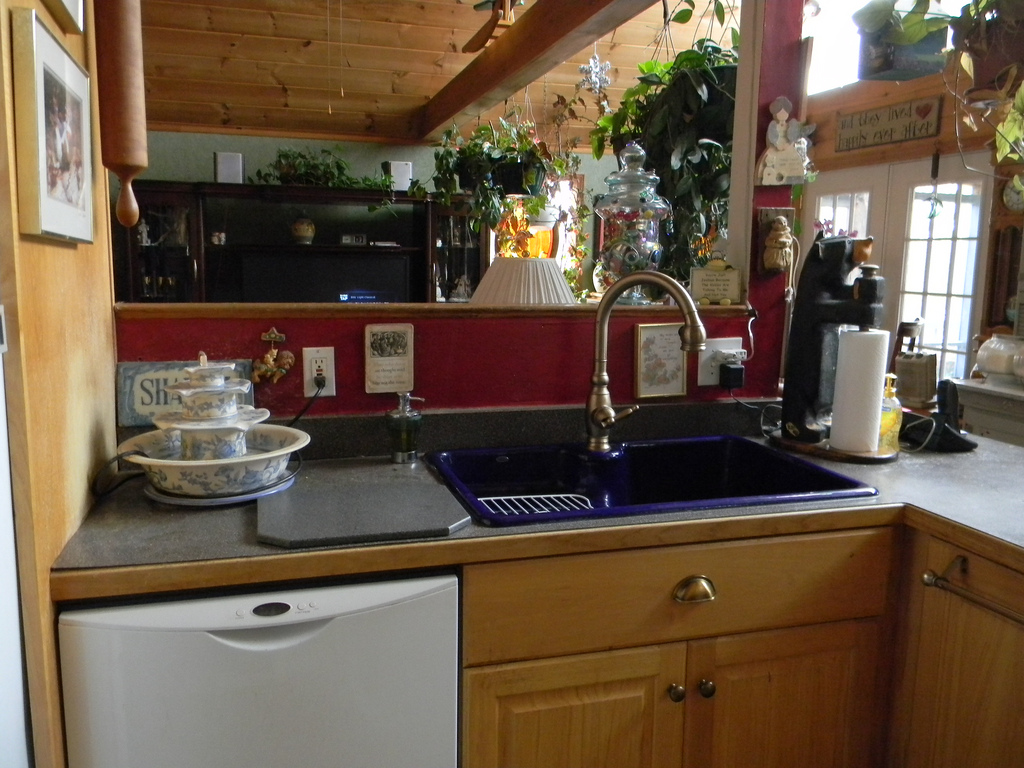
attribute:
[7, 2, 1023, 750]
kitchen — open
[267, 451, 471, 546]
chopping board — clean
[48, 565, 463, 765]
dishwasher — white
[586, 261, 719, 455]
faucet — metal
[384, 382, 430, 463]
soap dispenser — small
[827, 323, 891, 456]
paper towel — roll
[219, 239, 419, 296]
tv — off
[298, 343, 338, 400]
power outlet — convenient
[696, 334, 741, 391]
power outlet — convenient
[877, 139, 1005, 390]
french door — white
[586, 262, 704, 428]
water faucet — arched, tall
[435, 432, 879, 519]
sink — blue, kitchen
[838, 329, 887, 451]
paper towels — roll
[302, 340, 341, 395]
face plate — white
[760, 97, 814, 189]
decorative piece — wooden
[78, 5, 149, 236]
rolling pin — wooden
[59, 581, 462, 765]
dishwasher — closed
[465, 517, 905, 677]
drawer — closed, wooden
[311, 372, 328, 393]
plug — black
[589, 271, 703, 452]
faucet — silver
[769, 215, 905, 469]
holder — wooden, bear shaped, paper towel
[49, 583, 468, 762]
dish washer — white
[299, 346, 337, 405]
electrical outlet — white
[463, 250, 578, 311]
lamp shade — white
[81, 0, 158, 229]
rolling pin — wooden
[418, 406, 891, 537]
sink —  bright blue, ceramic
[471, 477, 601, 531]
rack — white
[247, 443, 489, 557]
cutting board — grey